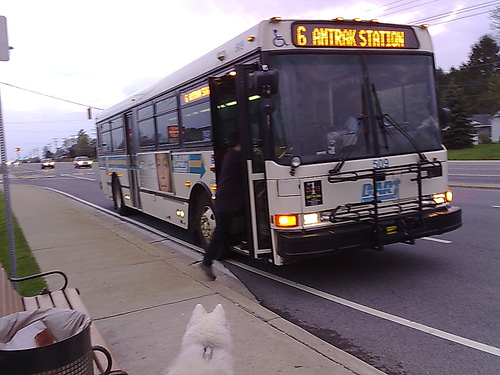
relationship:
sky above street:
[1, 3, 499, 161] [3, 158, 493, 368]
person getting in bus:
[196, 131, 254, 284] [96, 18, 459, 268]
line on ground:
[291, 271, 498, 364] [201, 167, 497, 371]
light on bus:
[300, 206, 326, 232] [96, 18, 459, 268]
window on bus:
[263, 46, 458, 155] [159, 2, 471, 244]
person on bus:
[100, 47, 430, 227] [154, 130, 252, 245]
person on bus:
[100, 47, 430, 227] [115, 85, 458, 259]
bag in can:
[17, 309, 68, 328] [0, 291, 136, 365]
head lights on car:
[56, 142, 109, 192] [73, 161, 102, 162]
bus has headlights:
[96, 18, 459, 268] [270, 211, 315, 231]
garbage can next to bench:
[3, 311, 93, 372] [1, 265, 126, 372]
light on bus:
[179, 82, 209, 102] [96, 18, 459, 268]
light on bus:
[310, 27, 359, 43] [96, 18, 459, 268]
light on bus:
[274, 213, 297, 229] [96, 18, 459, 268]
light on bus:
[428, 191, 451, 203] [96, 18, 459, 268]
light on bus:
[170, 209, 184, 218] [96, 18, 459, 268]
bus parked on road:
[96, 18, 459, 268] [23, 154, 495, 368]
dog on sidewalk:
[169, 289, 235, 372] [12, 184, 382, 373]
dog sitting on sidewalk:
[169, 289, 235, 372] [17, 175, 403, 370]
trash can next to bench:
[3, 308, 95, 372] [1, 265, 126, 372]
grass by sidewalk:
[0, 190, 55, 298] [17, 175, 403, 370]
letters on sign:
[296, 24, 403, 46] [289, 21, 424, 48]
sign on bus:
[290, 19, 419, 49] [96, 18, 459, 268]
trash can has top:
[3, 308, 95, 372] [0, 308, 93, 356]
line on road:
[291, 271, 498, 364] [23, 154, 495, 368]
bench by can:
[0, 253, 126, 373] [0, 308, 100, 373]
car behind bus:
[40, 158, 55, 168] [96, 18, 459, 268]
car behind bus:
[70, 153, 93, 168] [96, 18, 459, 268]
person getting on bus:
[196, 131, 254, 284] [96, 18, 459, 268]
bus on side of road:
[96, 18, 459, 268] [23, 154, 495, 368]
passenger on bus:
[188, 126, 273, 276] [62, 39, 480, 279]